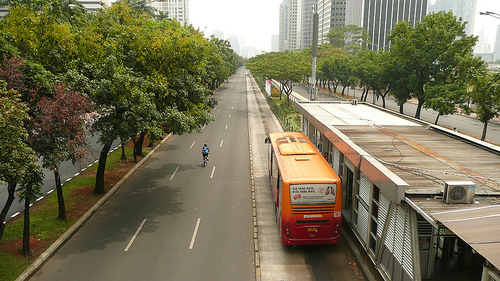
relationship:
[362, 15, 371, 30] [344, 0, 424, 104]
window of buiding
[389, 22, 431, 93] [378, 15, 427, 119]
leaves of tree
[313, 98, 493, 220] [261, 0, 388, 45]
roof of building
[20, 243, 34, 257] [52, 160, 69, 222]
trunk of tree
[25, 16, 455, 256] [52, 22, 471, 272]
picture taken outdoors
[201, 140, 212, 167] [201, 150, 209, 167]
bicyclist riding bicycle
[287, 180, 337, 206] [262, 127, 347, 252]
advertisement on bus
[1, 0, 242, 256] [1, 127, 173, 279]
tree row planted in median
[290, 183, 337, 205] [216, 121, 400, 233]
advertisement on back bus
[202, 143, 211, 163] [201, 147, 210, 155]
bicyclist wearing blue riding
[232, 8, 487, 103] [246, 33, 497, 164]
trees in median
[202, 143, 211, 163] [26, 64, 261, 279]
bicyclist on highway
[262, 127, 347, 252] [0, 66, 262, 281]
bus parked on side highway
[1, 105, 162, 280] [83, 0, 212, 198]
median filled with tree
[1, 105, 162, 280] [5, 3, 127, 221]
median filled with tree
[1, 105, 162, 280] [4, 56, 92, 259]
median filled with tree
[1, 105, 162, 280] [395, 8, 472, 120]
median filled with tree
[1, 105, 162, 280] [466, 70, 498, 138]
median filled with tree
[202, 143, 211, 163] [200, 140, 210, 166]
bicyclist riding bicycle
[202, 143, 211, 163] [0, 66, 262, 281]
bicyclist in middle of highway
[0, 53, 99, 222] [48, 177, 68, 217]
tree has trunk